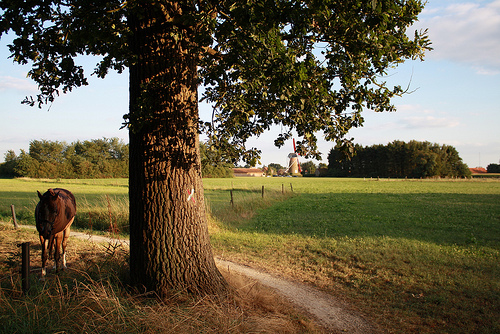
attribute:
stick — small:
[260, 185, 264, 198]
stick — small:
[279, 182, 285, 193]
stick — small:
[289, 182, 295, 193]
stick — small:
[227, 191, 234, 208]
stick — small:
[229, 179, 234, 189]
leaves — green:
[369, 89, 400, 116]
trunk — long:
[129, 60, 230, 294]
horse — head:
[29, 184, 78, 280]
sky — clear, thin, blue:
[388, 29, 498, 106]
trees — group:
[322, 136, 476, 179]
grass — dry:
[37, 260, 290, 330]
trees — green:
[325, 132, 467, 180]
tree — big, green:
[0, 0, 437, 303]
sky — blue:
[2, 0, 495, 170]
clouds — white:
[372, 103, 461, 148]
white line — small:
[184, 185, 197, 205]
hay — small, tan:
[322, 232, 462, 312]